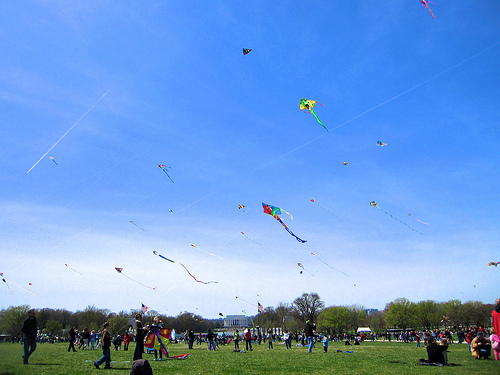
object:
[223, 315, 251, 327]
building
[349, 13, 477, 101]
sky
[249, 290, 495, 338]
trees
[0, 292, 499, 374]
park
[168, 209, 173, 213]
kite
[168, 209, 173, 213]
kites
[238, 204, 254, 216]
kite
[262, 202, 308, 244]
colorful kite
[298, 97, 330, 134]
colorful kite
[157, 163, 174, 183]
colorful kite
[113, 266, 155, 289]
colorful kite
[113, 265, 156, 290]
kite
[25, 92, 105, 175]
jet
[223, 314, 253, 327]
washington monument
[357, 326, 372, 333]
tent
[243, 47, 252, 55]
kite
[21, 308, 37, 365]
man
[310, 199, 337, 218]
kite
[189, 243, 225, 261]
kite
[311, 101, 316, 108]
yellow and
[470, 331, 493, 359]
person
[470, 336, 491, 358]
jacket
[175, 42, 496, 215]
trail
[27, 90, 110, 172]
trail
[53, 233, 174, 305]
cloud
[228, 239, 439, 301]
cloud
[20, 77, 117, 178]
streak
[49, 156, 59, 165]
kite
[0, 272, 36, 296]
kite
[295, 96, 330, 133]
kite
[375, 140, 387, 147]
kite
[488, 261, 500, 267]
kite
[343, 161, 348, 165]
kite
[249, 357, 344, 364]
lawn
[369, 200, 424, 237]
kite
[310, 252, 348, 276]
kite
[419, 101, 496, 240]
sky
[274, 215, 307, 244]
tail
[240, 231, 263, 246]
kite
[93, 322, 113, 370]
boy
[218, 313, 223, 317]
kite string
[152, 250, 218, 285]
kite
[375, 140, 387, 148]
kite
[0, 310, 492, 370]
people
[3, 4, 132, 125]
sky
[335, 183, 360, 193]
cloud